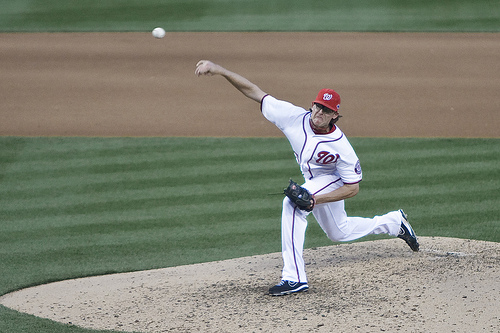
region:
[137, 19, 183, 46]
White baseball in the air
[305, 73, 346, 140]
Man wearing a red hat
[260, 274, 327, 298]
Black and white shoes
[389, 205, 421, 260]
Black and white shoe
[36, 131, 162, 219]
Patch of green turf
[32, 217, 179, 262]
Patch of green turf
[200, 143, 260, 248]
Patch of green turf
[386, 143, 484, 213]
Patch of green turf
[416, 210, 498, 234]
Patch of green turf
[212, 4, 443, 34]
Patch of green turf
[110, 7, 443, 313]
man is playing baseball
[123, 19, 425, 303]
man is throwing the ball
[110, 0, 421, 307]
the man is pitching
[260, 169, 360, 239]
man is wearing a glove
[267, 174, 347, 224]
the glove is black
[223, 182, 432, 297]
man is wearing sneakers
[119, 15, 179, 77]
the ball is white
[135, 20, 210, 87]
the ball is in the air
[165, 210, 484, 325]
the pitchers mound is tan with black specs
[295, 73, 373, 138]
the man is wearing a baseball cap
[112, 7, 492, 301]
a man playing baseball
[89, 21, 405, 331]
a man throwing a baseball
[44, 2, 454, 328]
a man pitching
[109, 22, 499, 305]
a pitcher throwing a baseball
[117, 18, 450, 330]
a pitcher that is pitching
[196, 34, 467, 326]
a man in a uniform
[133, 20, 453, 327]
a man in a baseball uniform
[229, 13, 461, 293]
a man wearing red hat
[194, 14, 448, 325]
a man wearing a baseball mitt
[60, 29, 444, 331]
a man in a pitcher circle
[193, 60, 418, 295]
Pitcher immediatly after throwing baseball on mound.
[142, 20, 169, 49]
baseball in mid-air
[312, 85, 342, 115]
red and white baseball cap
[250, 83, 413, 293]
red and white uniform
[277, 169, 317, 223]
black leather baseball glove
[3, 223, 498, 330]
white sand pitcher's mound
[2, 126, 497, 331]
manicured baseball field grass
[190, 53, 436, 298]
baseball pitcher making a throw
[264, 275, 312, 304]
men's black athletic footwear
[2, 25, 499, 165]
dirt area portion of baseball diamond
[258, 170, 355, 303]
left leg thrust forward